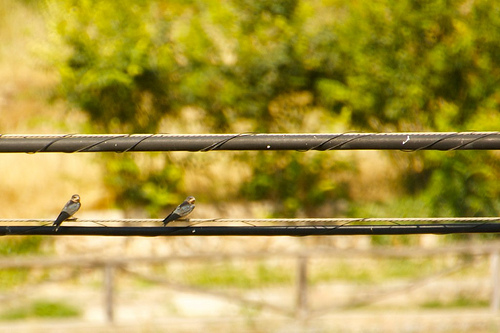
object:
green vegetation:
[0, 0, 499, 332]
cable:
[0, 224, 498, 237]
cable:
[0, 134, 499, 154]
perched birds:
[50, 194, 82, 233]